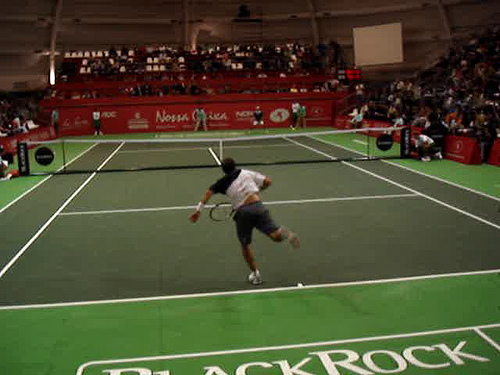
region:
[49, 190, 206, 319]
tennis court is green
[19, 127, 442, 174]
tennis net in middle of court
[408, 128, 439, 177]
person to retrieve the tennis balls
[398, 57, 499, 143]
spectators watching the game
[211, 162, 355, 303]
tennis player's leg in the air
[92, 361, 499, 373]
BLACKROCK is written on the court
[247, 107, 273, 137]
tennis player watching the tennis ball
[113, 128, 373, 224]
white lines on the tennis court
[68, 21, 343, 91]
lights on in the building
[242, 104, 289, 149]
tennis player is wearing white shorts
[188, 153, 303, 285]
Tennis player just served the ball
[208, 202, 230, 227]
Tennis racket head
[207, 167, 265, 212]
Black and white shirt of tennis player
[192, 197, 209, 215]
White wristband of tennis player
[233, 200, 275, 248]
Blue shorts of tennis player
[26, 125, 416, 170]
Tennis court net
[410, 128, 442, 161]
Ball boy at tennis match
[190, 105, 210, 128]
Linesman at tennis match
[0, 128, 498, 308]
Green tennis court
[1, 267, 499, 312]
White baseline on tennis court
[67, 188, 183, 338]
tennis turf is grey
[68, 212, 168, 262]
tennis turf is grey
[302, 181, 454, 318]
tennis turf is grey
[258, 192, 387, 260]
tennis turf is grey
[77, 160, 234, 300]
tennis turf is grey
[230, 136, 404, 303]
tennis turf is grey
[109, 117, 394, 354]
tennis turf is grey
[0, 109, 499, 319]
clay tennis court painted green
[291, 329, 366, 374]
tennis court with the letter R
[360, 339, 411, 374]
the letter o on the green tennis court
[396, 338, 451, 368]
the letter c on a green tennis court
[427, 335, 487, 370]
the letter k on a green tennis court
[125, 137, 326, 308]
man playing tennis on a clay court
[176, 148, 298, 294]
man holding a tennis racquet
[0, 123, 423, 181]
black tennis net on a green court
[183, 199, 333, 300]
man wearing white tennis shoes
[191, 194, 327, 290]
man wearing gray tennis shorts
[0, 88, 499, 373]
A green tennis court.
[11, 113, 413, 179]
A black and white tennis net.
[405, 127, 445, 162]
A man in a white shirt squatting next to the net.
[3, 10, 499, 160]
A group of people watching the tennis match.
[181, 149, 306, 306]
A man running on the tennis court.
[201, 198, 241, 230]
A black tennis racket held by the man.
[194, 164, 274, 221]
A black and white shirt worn by the man.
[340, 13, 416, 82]
A white screen hanging from the ceiling.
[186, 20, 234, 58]
A shadow on the wall.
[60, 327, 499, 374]
The word "BlackRock" on the tennis court.